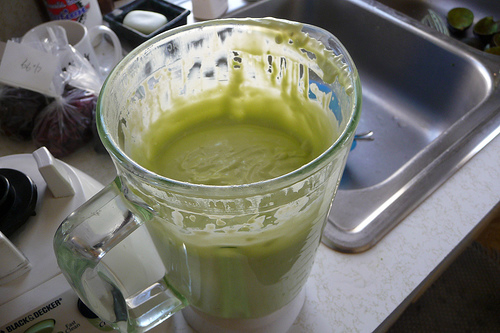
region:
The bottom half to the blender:
[1, 145, 186, 330]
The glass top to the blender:
[49, 11, 364, 328]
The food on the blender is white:
[168, 93, 285, 185]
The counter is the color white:
[324, 271, 376, 329]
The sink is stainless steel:
[368, 40, 450, 127]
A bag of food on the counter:
[28, 74, 90, 151]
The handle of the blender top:
[50, 173, 192, 330]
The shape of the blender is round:
[92, 12, 369, 197]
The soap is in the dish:
[101, 0, 194, 41]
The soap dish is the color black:
[104, 0, 185, 41]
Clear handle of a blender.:
[53, 175, 185, 331]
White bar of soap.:
[120, 9, 165, 34]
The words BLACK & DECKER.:
[2, 297, 66, 331]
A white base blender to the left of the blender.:
[0, 154, 165, 331]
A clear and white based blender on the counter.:
[53, 17, 363, 332]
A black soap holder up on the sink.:
[104, 0, 189, 47]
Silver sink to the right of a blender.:
[158, 0, 498, 250]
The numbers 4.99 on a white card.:
[17, 57, 42, 75]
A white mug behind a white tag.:
[18, 23, 123, 80]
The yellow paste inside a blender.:
[163, 115, 313, 185]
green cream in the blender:
[138, 114, 285, 231]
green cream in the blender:
[98, 39, 345, 256]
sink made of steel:
[323, 18, 480, 260]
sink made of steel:
[220, 26, 440, 331]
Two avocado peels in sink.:
[445, 5, 496, 42]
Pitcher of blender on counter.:
[55, 15, 350, 326]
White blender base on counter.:
[0, 145, 110, 330]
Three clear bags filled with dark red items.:
[0, 31, 115, 153]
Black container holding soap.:
[100, 0, 190, 35]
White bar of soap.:
[120, 5, 165, 25]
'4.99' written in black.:
[16, 55, 41, 75]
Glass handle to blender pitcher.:
[55, 187, 170, 327]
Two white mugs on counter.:
[24, 2, 126, 68]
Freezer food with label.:
[6, 37, 92, 154]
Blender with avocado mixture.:
[57, 17, 368, 331]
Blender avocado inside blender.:
[155, 94, 295, 177]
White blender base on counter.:
[0, 146, 176, 330]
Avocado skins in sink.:
[439, 9, 498, 51]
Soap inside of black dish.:
[127, 11, 167, 30]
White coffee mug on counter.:
[22, 17, 124, 82]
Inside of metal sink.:
[207, 0, 486, 192]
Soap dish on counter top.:
[97, 0, 197, 45]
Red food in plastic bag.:
[5, 34, 97, 158]